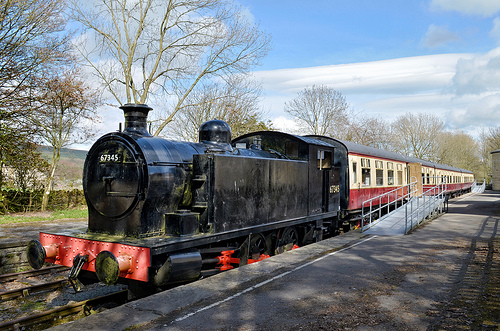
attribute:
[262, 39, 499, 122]
clouds —  white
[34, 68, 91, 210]
tree — small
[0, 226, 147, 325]
rail track — concrete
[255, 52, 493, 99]
clouds —  white 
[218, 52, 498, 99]
white clouds —  white 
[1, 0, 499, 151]
sky —  blue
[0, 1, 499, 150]
clouds —  white 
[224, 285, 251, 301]
line — white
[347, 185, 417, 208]
car bottom — red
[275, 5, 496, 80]
sky —  blue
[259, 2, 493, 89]
sky —  blue